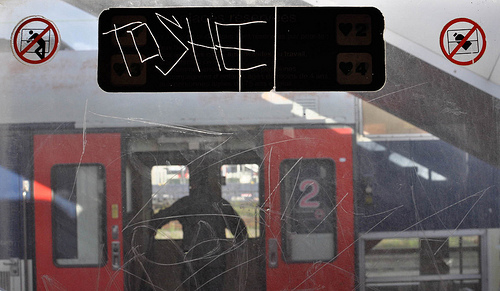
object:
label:
[439, 18, 485, 65]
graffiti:
[108, 8, 270, 91]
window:
[0, 3, 499, 289]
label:
[10, 15, 60, 64]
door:
[263, 123, 357, 290]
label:
[337, 15, 369, 47]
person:
[150, 156, 246, 289]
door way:
[122, 132, 266, 290]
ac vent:
[293, 96, 318, 119]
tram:
[0, 46, 499, 291]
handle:
[268, 236, 278, 267]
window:
[281, 159, 338, 261]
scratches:
[100, 211, 256, 290]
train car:
[0, 124, 360, 291]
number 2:
[298, 179, 322, 209]